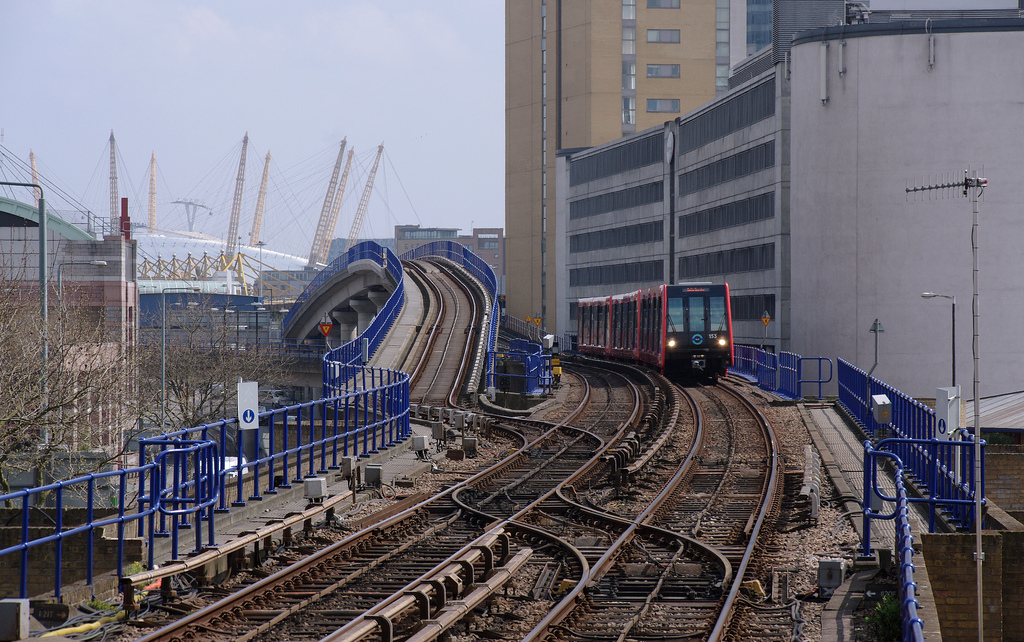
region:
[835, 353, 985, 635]
the railing is blue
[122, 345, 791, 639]
the tracks are rusty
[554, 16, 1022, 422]
the building is grey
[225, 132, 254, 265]
a crane is in the air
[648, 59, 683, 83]
a window on the yellow building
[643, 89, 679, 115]
a window on a yellow building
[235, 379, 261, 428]
sign with a blue logo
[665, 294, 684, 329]
the front window of a train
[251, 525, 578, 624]
Bunch of vacant train tracks.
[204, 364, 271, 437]
White sign on the side above the rail.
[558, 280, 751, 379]
Red train coming down the tracks.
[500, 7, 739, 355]
Tall brow building with windows on it.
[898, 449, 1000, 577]
Shadow of the awning on the ground.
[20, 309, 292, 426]
Trees in the concrete without leaves.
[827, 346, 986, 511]
blue gate near the train tracks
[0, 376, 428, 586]
blue iron fence near the train tracks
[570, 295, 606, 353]
third car of a red train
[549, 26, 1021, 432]
large white building alongside the train tracks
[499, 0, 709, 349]
tall brown building behind the white building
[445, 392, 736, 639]
curvy train tracks going towards a hill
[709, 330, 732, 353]
headlight on a red train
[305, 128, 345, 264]
metal arm holding up roof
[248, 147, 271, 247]
metal arm holding up roof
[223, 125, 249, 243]
metal arm holding up roof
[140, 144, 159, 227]
metal arm holding up roof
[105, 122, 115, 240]
metal arm holding up roof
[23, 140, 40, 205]
metal arm holding up roof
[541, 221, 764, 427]
a red train on track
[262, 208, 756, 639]
a very curvy track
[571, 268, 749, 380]
red and black colored train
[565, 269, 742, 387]
train on a track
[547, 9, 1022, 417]
white building near a train track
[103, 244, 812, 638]
sets of train tracks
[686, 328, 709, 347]
blue logo on the front of the train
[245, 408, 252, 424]
white arrow on a sign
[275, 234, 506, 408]
rail on a bridge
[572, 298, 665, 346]
row of windows on the side of a train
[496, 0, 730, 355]
tall brown building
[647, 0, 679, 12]
window on tall building facing train track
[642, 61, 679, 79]
window on tall building facing train track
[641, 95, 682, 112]
window on tall building facing train track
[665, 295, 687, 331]
windown in front of red and black train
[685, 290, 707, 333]
windown in front of red and black train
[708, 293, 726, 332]
windown in front of red and black train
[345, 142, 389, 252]
crane behind train track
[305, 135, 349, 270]
crane behind train track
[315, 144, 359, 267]
crane behind train track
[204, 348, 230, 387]
green leaves on the tree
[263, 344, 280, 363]
green leaves on the tree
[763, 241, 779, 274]
a window on the building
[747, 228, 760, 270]
a window on the building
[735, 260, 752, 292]
a window on the building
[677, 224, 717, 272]
a window on the building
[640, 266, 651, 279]
a window on the building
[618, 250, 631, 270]
a window on the building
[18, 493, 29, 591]
blue pole on railing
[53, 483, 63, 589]
blue pole on railing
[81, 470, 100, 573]
blue pole on railing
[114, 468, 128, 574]
blue pole on railing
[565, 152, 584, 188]
window on a building